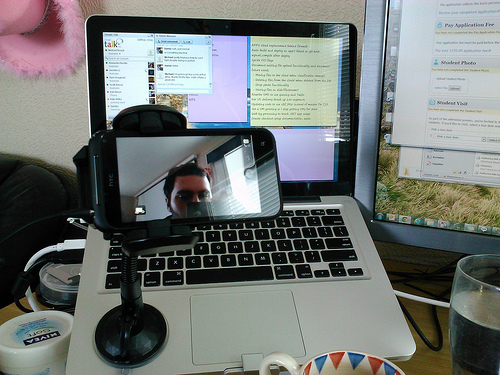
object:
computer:
[63, 19, 415, 374]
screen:
[117, 134, 262, 221]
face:
[169, 176, 212, 215]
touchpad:
[186, 291, 302, 365]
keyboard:
[105, 208, 364, 289]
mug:
[260, 350, 407, 373]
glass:
[445, 248, 500, 371]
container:
[0, 311, 74, 375]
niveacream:
[1, 309, 73, 375]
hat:
[1, 1, 83, 79]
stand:
[71, 217, 167, 367]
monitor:
[353, 3, 497, 260]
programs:
[424, 218, 436, 228]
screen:
[104, 19, 340, 184]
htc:
[108, 173, 116, 186]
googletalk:
[105, 41, 118, 49]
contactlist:
[105, 61, 125, 115]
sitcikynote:
[250, 40, 340, 126]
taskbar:
[378, 211, 498, 237]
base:
[93, 303, 168, 368]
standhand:
[75, 103, 191, 369]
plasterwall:
[0, 0, 357, 200]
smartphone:
[92, 126, 282, 232]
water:
[447, 289, 499, 366]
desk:
[3, 194, 499, 370]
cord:
[22, 237, 87, 313]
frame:
[85, 17, 357, 38]